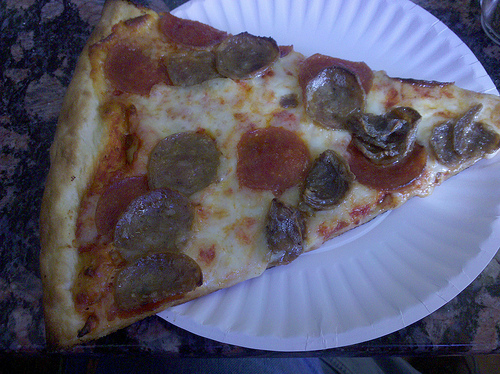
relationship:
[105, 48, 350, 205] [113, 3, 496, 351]
pizza on plate